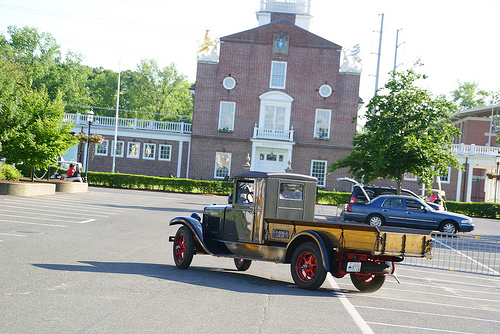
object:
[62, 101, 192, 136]
railing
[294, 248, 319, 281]
red rim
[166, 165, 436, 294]
truck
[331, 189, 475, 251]
car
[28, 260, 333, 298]
shadow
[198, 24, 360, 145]
wall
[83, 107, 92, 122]
chairs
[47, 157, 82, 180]
golf cart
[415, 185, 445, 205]
golf cart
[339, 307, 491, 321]
white lines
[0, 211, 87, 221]
white lines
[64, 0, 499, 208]
brick buildnig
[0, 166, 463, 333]
parking lot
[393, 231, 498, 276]
railing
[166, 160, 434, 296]
car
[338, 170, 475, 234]
blue car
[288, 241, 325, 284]
tire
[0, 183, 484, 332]
lot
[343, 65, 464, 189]
tree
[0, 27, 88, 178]
tree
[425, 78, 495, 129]
tree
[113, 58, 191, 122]
tree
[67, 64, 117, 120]
tree